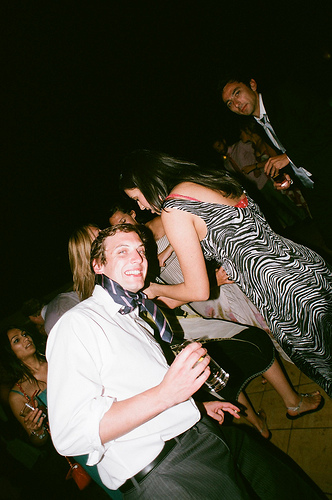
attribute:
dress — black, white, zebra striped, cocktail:
[160, 197, 328, 397]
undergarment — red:
[164, 192, 250, 208]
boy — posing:
[37, 222, 326, 494]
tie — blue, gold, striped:
[92, 270, 173, 344]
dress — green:
[11, 388, 51, 418]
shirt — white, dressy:
[43, 286, 208, 490]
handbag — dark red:
[61, 457, 93, 489]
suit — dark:
[259, 92, 331, 227]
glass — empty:
[197, 363, 235, 396]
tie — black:
[129, 308, 173, 336]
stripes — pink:
[158, 319, 170, 331]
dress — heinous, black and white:
[216, 219, 310, 333]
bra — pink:
[167, 191, 210, 209]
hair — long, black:
[0, 351, 30, 374]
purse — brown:
[63, 464, 96, 488]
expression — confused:
[10, 333, 37, 345]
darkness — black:
[10, 155, 60, 214]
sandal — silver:
[290, 391, 321, 414]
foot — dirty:
[305, 391, 322, 410]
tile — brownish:
[284, 423, 319, 450]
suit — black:
[257, 88, 329, 203]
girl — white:
[113, 143, 331, 361]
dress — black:
[157, 171, 330, 376]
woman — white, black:
[114, 140, 331, 381]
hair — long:
[114, 142, 246, 198]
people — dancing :
[2, 70, 330, 488]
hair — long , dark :
[130, 153, 187, 191]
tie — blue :
[125, 287, 185, 358]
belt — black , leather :
[114, 460, 171, 473]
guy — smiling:
[86, 225, 155, 297]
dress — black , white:
[172, 195, 329, 330]